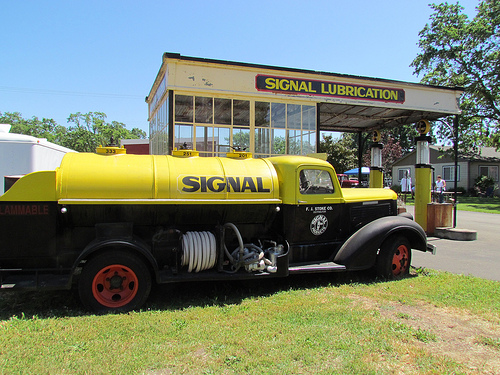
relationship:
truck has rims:
[0, 135, 436, 314] [67, 230, 439, 333]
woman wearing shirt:
[434, 175, 446, 190] [435, 179, 444, 189]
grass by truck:
[0, 270, 495, 370] [10, 146, 411, 296]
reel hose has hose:
[162, 207, 224, 276] [186, 230, 211, 264]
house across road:
[389, 143, 499, 197] [393, 181, 484, 254]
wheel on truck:
[77, 244, 147, 313] [0, 135, 436, 314]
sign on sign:
[252, 75, 410, 104] [251, 73, 408, 103]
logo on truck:
[178, 176, 270, 196] [0, 135, 436, 314]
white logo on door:
[295, 203, 343, 240] [296, 163, 343, 263]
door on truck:
[296, 163, 343, 263] [0, 135, 436, 314]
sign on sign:
[252, 75, 410, 104] [249, 77, 420, 112]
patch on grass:
[331, 283, 498, 372] [42, 317, 217, 359]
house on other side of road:
[389, 141, 498, 189] [393, 200, 500, 284]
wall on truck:
[202, 77, 245, 99] [0, 135, 436, 314]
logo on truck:
[178, 176, 270, 196] [34, 124, 411, 276]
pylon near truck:
[367, 166, 384, 188] [50, 143, 412, 299]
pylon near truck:
[413, 164, 431, 234] [50, 143, 412, 299]